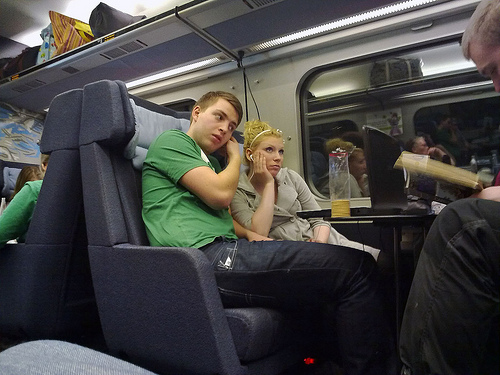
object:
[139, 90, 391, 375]
guy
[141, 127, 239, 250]
shirt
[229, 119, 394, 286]
woman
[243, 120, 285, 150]
hair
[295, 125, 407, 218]
laptop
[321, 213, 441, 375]
table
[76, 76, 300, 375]
seat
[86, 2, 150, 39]
bag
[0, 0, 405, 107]
shelf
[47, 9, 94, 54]
bag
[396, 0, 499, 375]
man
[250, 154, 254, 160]
ear bud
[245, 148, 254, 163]
ear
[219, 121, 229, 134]
nose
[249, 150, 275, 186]
right hand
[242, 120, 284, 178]
head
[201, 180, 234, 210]
right elbow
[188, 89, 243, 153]
head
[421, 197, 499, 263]
left knee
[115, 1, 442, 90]
overhead light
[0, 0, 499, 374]
train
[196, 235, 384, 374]
blue jeans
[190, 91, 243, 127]
hair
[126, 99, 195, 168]
cushion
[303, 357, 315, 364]
light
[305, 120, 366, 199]
reflection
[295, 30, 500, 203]
window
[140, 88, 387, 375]
couple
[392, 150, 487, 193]
book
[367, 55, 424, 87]
duffle bag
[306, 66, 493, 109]
shelf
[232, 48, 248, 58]
electrical outlet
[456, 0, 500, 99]
head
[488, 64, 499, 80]
eye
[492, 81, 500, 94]
nose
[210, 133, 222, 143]
mouth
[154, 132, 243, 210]
arm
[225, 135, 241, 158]
hand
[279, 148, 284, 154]
eye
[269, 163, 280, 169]
mouth